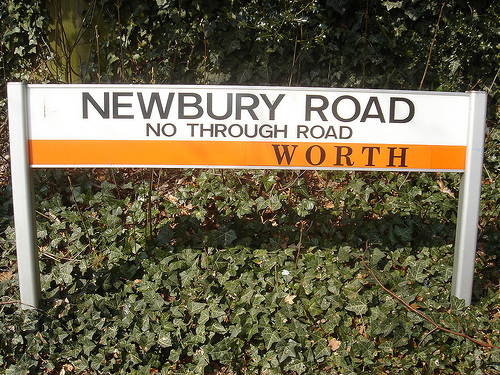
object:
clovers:
[203, 252, 271, 290]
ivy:
[8, 167, 500, 375]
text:
[82, 92, 415, 167]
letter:
[271, 144, 298, 165]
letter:
[305, 144, 325, 165]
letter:
[333, 146, 354, 167]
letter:
[362, 146, 381, 166]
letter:
[386, 147, 409, 168]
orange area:
[27, 139, 466, 169]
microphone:
[5, 77, 486, 322]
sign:
[21, 83, 467, 174]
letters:
[146, 123, 352, 140]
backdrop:
[27, 139, 466, 170]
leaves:
[59, 244, 106, 282]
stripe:
[26, 139, 467, 170]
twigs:
[416, 309, 498, 348]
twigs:
[294, 220, 308, 268]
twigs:
[144, 200, 152, 238]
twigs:
[150, 170, 161, 192]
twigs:
[63, 171, 92, 253]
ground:
[0, 72, 500, 375]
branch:
[367, 265, 496, 349]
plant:
[3, 308, 500, 375]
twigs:
[362, 260, 454, 345]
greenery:
[315, 285, 403, 351]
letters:
[82, 91, 109, 119]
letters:
[112, 92, 134, 119]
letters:
[137, 92, 175, 119]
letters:
[178, 92, 204, 119]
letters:
[207, 92, 233, 119]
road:
[297, 125, 353, 139]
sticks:
[37, 25, 84, 77]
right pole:
[451, 89, 488, 304]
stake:
[5, 82, 41, 310]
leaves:
[364, 331, 419, 364]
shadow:
[91, 211, 495, 292]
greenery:
[118, 222, 196, 261]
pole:
[4, 80, 40, 310]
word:
[271, 144, 409, 167]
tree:
[45, 1, 94, 85]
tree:
[303, 0, 392, 89]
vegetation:
[71, 288, 367, 366]